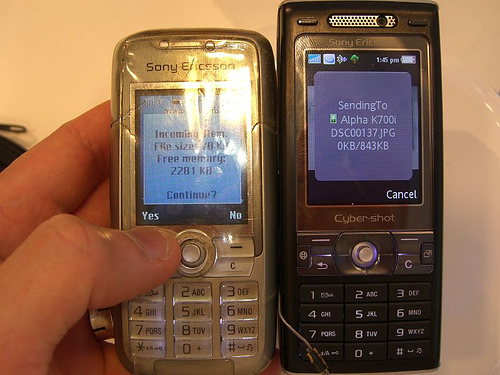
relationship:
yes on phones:
[139, 208, 160, 221] [110, 0, 444, 375]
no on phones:
[228, 207, 245, 220] [110, 0, 444, 375]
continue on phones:
[165, 187, 209, 202] [110, 0, 444, 375]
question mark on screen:
[210, 188, 218, 203] [138, 88, 248, 225]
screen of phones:
[138, 88, 248, 225] [110, 0, 444, 375]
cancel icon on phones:
[385, 187, 419, 200] [110, 0, 444, 375]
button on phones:
[352, 239, 378, 267] [110, 0, 444, 375]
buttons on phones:
[127, 237, 259, 358] [110, 0, 444, 375]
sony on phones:
[144, 58, 177, 73] [110, 0, 444, 375]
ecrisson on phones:
[183, 56, 232, 71] [110, 0, 444, 375]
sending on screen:
[337, 100, 373, 112] [304, 52, 423, 203]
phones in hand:
[112, 3, 444, 374] [2, 104, 444, 375]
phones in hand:
[110, 0, 444, 375] [1, 100, 177, 375]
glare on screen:
[184, 80, 249, 167] [138, 88, 248, 225]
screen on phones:
[138, 88, 248, 225] [110, 0, 444, 375]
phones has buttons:
[110, 0, 444, 375] [123, 239, 259, 358]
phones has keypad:
[110, 0, 444, 375] [302, 281, 433, 367]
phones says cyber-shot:
[110, 0, 444, 375] [335, 209, 399, 226]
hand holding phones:
[1, 100, 177, 375] [112, 3, 444, 374]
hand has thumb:
[1, 100, 177, 375] [2, 215, 180, 331]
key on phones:
[224, 338, 258, 355] [110, 0, 444, 375]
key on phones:
[131, 339, 164, 356] [110, 0, 444, 375]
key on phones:
[175, 341, 209, 354] [110, 0, 444, 375]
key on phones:
[131, 320, 163, 339] [110, 0, 444, 375]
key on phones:
[174, 318, 211, 339] [110, 0, 444, 375]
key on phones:
[129, 300, 163, 320] [110, 0, 444, 375]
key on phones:
[222, 301, 257, 321] [110, 0, 444, 375]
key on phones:
[174, 304, 210, 321] [110, 0, 444, 375]